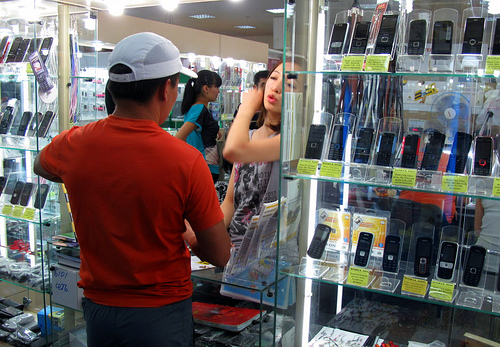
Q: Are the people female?
A: No, they are both male and female.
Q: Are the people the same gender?
A: No, they are both male and female.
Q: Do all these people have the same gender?
A: No, they are both male and female.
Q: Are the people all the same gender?
A: No, they are both male and female.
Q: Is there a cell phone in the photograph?
A: Yes, there is a cell phone.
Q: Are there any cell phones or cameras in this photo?
A: Yes, there is a cell phone.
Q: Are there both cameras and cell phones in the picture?
A: No, there is a cell phone but no cameras.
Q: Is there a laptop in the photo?
A: No, there are no laptops.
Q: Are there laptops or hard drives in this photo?
A: No, there are no laptops or hard drives.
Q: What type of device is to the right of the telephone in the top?
A: The device is a cell phone.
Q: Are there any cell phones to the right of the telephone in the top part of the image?
A: Yes, there is a cell phone to the right of the phone.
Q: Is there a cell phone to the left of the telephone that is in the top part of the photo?
A: No, the cell phone is to the right of the telephone.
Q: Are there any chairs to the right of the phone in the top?
A: No, there is a cell phone to the right of the telephone.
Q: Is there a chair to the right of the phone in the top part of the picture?
A: No, there is a cell phone to the right of the telephone.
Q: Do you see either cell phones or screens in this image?
A: Yes, there is a cell phone.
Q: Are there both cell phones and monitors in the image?
A: No, there is a cell phone but no monitors.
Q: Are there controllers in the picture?
A: No, there are no controllers.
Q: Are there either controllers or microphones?
A: No, there are no controllers or microphones.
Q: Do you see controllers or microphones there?
A: No, there are no controllers or microphones.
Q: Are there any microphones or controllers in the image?
A: No, there are no controllers or microphones.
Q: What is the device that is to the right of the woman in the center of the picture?
A: The device is a cell phone.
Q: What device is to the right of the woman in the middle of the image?
A: The device is a cell phone.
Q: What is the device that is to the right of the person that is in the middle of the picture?
A: The device is a cell phone.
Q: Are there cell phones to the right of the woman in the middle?
A: Yes, there is a cell phone to the right of the woman.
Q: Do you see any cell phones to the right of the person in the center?
A: Yes, there is a cell phone to the right of the woman.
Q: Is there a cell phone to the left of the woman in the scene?
A: No, the cell phone is to the right of the woman.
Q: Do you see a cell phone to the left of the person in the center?
A: No, the cell phone is to the right of the woman.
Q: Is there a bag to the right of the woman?
A: No, there is a cell phone to the right of the woman.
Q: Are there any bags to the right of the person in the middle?
A: No, there is a cell phone to the right of the woman.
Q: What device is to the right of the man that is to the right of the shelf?
A: The device is a cell phone.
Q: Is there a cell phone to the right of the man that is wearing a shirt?
A: Yes, there is a cell phone to the right of the man.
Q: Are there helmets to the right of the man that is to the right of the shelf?
A: No, there is a cell phone to the right of the man.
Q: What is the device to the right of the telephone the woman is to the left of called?
A: The device is a cell phone.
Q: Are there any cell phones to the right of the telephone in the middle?
A: Yes, there is a cell phone to the right of the telephone.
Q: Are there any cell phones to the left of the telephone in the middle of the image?
A: No, the cell phone is to the right of the telephone.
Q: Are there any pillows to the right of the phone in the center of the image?
A: No, there is a cell phone to the right of the telephone.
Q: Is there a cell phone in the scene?
A: Yes, there is a cell phone.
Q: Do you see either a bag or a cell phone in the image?
A: Yes, there is a cell phone.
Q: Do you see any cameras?
A: No, there are no cameras.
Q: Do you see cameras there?
A: No, there are no cameras.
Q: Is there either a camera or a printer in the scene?
A: No, there are no cameras or printers.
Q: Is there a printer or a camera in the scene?
A: No, there are no cameras or printers.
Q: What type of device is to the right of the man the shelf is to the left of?
A: The device is a cell phone.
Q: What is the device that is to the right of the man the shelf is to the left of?
A: The device is a cell phone.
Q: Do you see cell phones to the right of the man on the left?
A: Yes, there is a cell phone to the right of the man.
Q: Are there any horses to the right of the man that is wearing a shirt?
A: No, there is a cell phone to the right of the man.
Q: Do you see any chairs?
A: No, there are no chairs.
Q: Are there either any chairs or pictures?
A: No, there are no chairs or pictures.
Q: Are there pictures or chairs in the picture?
A: No, there are no chairs or pictures.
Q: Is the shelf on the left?
A: Yes, the shelf is on the left of the image.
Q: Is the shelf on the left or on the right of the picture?
A: The shelf is on the left of the image.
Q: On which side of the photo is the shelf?
A: The shelf is on the left of the image.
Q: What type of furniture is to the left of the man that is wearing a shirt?
A: The piece of furniture is a shelf.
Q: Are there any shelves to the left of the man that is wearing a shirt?
A: Yes, there is a shelf to the left of the man.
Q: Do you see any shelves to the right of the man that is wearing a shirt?
A: No, the shelf is to the left of the man.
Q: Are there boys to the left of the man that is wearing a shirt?
A: No, there is a shelf to the left of the man.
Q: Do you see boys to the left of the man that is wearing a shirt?
A: No, there is a shelf to the left of the man.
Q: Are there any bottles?
A: No, there are no bottles.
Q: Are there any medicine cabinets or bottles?
A: No, there are no bottles or medicine cabinets.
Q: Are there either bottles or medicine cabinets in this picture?
A: No, there are no bottles or medicine cabinets.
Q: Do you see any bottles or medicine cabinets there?
A: No, there are no bottles or medicine cabinets.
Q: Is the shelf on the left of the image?
A: Yes, the shelf is on the left of the image.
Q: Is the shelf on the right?
A: No, the shelf is on the left of the image.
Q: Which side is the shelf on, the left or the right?
A: The shelf is on the left of the image.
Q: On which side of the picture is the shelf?
A: The shelf is on the left of the image.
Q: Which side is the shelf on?
A: The shelf is on the left of the image.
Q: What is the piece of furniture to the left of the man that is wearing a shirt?
A: The piece of furniture is a shelf.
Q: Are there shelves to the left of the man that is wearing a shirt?
A: Yes, there is a shelf to the left of the man.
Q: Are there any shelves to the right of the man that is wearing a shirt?
A: No, the shelf is to the left of the man.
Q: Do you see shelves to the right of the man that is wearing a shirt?
A: No, the shelf is to the left of the man.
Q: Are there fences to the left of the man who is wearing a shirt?
A: No, there is a shelf to the left of the man.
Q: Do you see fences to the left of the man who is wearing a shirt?
A: No, there is a shelf to the left of the man.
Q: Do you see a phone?
A: Yes, there is a phone.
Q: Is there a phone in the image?
A: Yes, there is a phone.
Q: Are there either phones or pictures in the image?
A: Yes, there is a phone.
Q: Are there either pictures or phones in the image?
A: Yes, there is a phone.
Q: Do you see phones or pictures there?
A: Yes, there is a phone.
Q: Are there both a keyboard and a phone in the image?
A: Yes, there are both a phone and a keyboard.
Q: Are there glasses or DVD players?
A: No, there are no glasses or DVD players.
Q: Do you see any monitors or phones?
A: Yes, there is a phone.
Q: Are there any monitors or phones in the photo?
A: Yes, there is a phone.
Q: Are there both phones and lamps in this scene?
A: No, there is a phone but no lamps.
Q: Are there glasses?
A: No, there are no glasses.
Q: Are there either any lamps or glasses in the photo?
A: No, there are no glasses or lamps.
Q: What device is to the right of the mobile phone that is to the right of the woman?
A: The device is a phone.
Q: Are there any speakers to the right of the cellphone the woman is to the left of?
A: No, there is a phone to the right of the cell phone.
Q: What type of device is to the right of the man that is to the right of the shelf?
A: The device is a phone.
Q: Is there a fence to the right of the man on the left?
A: No, there is a phone to the right of the man.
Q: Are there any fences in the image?
A: No, there are no fences.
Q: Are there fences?
A: No, there are no fences.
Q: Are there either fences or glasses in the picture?
A: No, there are no fences or glasses.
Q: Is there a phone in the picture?
A: Yes, there is a phone.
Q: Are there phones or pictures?
A: Yes, there is a phone.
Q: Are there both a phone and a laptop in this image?
A: No, there is a phone but no laptops.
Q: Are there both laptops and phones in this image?
A: No, there is a phone but no laptops.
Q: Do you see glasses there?
A: No, there are no glasses.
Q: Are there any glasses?
A: No, there are no glasses.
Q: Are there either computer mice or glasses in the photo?
A: No, there are no glasses or computer mice.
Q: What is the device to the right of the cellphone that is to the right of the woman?
A: The device is a phone.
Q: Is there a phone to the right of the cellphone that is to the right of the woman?
A: Yes, there is a phone to the right of the cell phone.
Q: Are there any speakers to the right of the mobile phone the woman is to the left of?
A: No, there is a phone to the right of the cell phone.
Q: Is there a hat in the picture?
A: Yes, there is a hat.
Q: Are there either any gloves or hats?
A: Yes, there is a hat.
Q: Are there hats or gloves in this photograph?
A: Yes, there is a hat.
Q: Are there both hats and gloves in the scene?
A: No, there is a hat but no gloves.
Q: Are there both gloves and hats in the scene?
A: No, there is a hat but no gloves.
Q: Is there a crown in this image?
A: No, there are no crowns.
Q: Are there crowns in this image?
A: No, there are no crowns.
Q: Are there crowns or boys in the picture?
A: No, there are no crowns or boys.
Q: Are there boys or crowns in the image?
A: No, there are no crowns or boys.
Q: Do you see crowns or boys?
A: No, there are no crowns or boys.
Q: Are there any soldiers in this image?
A: No, there are no soldiers.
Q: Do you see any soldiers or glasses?
A: No, there are no soldiers or glasses.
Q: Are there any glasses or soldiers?
A: No, there are no soldiers or glasses.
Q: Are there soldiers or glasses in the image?
A: No, there are no soldiers or glasses.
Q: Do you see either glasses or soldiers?
A: No, there are no soldiers or glasses.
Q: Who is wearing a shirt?
A: The man is wearing a shirt.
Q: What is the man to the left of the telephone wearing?
A: The man is wearing a shirt.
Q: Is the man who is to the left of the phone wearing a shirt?
A: Yes, the man is wearing a shirt.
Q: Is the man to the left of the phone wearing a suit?
A: No, the man is wearing a shirt.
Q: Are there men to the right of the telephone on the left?
A: Yes, there is a man to the right of the phone.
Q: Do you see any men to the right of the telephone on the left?
A: Yes, there is a man to the right of the phone.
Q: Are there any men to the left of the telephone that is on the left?
A: No, the man is to the right of the telephone.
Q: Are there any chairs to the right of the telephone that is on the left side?
A: No, there is a man to the right of the telephone.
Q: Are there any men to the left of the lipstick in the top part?
A: Yes, there is a man to the left of the lipstick.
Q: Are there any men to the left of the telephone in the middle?
A: Yes, there is a man to the left of the phone.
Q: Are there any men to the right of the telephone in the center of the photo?
A: No, the man is to the left of the phone.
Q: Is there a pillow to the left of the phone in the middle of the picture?
A: No, there is a man to the left of the phone.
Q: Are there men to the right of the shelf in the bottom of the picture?
A: Yes, there is a man to the right of the shelf.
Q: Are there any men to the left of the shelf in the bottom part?
A: No, the man is to the right of the shelf.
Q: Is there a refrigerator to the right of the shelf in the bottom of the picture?
A: No, there is a man to the right of the shelf.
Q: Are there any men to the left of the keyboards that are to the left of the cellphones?
A: Yes, there is a man to the left of the keyboards.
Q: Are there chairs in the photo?
A: No, there are no chairs.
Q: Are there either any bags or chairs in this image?
A: No, there are no chairs or bags.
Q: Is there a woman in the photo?
A: Yes, there is a woman.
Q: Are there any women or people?
A: Yes, there is a woman.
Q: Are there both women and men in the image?
A: Yes, there are both a woman and a man.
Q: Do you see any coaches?
A: No, there are no coaches.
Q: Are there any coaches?
A: No, there are no coaches.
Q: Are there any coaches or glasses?
A: No, there are no coaches or glasses.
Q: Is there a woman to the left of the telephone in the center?
A: Yes, there is a woman to the left of the phone.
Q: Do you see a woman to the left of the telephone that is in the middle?
A: Yes, there is a woman to the left of the phone.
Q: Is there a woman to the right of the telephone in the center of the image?
A: No, the woman is to the left of the phone.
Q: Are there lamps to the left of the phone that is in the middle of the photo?
A: No, there is a woman to the left of the telephone.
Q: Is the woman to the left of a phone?
A: Yes, the woman is to the left of a phone.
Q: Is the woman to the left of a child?
A: No, the woman is to the left of a phone.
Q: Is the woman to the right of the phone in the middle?
A: No, the woman is to the left of the phone.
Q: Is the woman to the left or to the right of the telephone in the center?
A: The woman is to the left of the phone.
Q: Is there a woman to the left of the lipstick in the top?
A: Yes, there is a woman to the left of the lipstick.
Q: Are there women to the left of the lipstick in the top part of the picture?
A: Yes, there is a woman to the left of the lipstick.